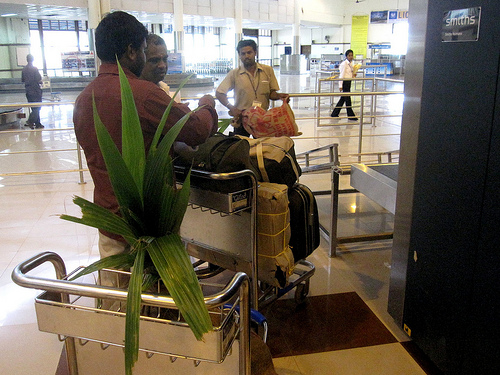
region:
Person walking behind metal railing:
[331, 48, 366, 121]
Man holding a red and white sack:
[238, 79, 299, 144]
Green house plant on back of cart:
[73, 107, 208, 344]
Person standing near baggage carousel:
[5, 55, 45, 129]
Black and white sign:
[434, 6, 489, 48]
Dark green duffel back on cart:
[160, 132, 254, 201]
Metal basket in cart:
[30, 259, 244, 371]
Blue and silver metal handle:
[207, 295, 277, 346]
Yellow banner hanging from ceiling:
[348, 11, 370, 65]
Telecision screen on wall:
[367, 6, 391, 26]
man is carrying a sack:
[210, 36, 327, 189]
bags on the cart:
[189, 122, 320, 329]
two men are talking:
[82, 12, 224, 179]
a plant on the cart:
[57, 96, 269, 370]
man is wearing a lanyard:
[226, 32, 279, 125]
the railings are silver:
[301, 80, 378, 180]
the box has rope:
[253, 171, 311, 300]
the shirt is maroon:
[57, 64, 199, 231]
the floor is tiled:
[20, 191, 103, 276]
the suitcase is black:
[278, 177, 331, 307]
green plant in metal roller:
[65, 46, 206, 356]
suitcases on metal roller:
[255, 175, 311, 285]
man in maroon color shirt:
[75, 12, 218, 219]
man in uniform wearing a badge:
[212, 38, 292, 140]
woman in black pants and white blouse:
[329, 45, 364, 122]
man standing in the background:
[21, 55, 44, 135]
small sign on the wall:
[440, 5, 485, 44]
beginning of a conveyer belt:
[353, 159, 398, 216]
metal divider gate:
[4, 127, 396, 189]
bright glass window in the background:
[28, 20, 90, 82]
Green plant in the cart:
[73, 142, 223, 313]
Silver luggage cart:
[66, 237, 281, 368]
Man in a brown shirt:
[68, 62, 187, 193]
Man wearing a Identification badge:
[251, 92, 264, 114]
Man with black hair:
[88, 6, 145, 68]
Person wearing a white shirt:
[336, 52, 355, 87]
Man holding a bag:
[243, 98, 298, 140]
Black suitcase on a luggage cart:
[275, 178, 335, 247]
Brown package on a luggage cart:
[263, 189, 295, 294]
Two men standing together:
[97, 12, 202, 234]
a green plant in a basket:
[103, 90, 213, 324]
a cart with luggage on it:
[177, 107, 347, 302]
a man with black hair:
[241, 31, 261, 70]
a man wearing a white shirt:
[337, 42, 358, 95]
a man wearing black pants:
[329, 45, 361, 116]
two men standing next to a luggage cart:
[111, 15, 222, 220]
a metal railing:
[0, 90, 70, 195]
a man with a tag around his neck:
[228, 29, 270, 129]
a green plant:
[113, 69, 201, 367]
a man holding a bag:
[216, 32, 298, 138]